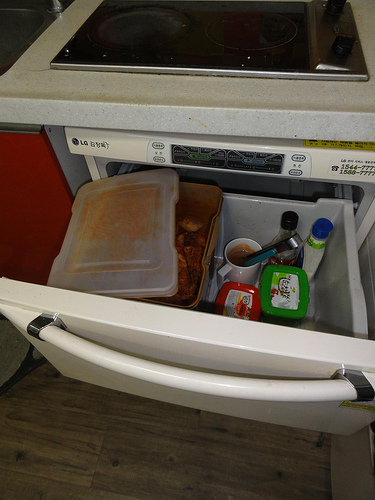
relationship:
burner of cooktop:
[100, 9, 183, 47] [52, 0, 370, 80]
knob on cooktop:
[330, 32, 357, 58] [52, 0, 370, 80]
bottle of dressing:
[302, 217, 331, 281] [300, 238, 324, 280]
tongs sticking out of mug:
[238, 233, 304, 265] [216, 238, 263, 283]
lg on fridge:
[70, 137, 91, 147] [3, 128, 374, 437]